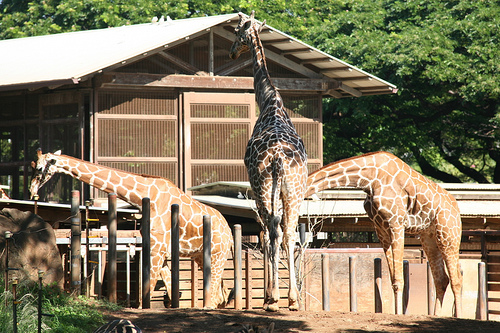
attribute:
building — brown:
[0, 12, 402, 195]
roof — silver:
[0, 8, 401, 102]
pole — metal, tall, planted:
[169, 203, 184, 311]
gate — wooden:
[176, 93, 261, 199]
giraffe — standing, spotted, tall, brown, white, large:
[227, 3, 312, 315]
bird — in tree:
[282, 7, 295, 19]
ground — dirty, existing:
[0, 288, 498, 332]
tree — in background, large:
[1, 1, 499, 183]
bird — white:
[148, 14, 159, 29]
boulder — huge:
[0, 199, 71, 305]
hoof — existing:
[264, 299, 284, 313]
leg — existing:
[385, 229, 411, 319]